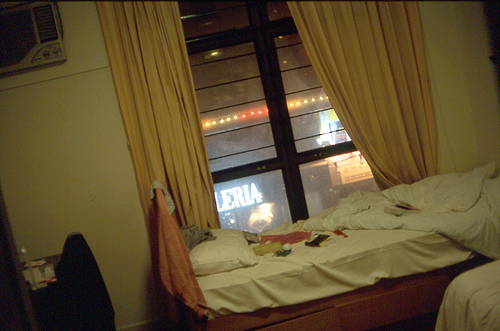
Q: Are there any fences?
A: No, there are no fences.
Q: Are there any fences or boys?
A: No, there are no fences or boys.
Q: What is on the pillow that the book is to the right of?
A: The shirt is on the pillow.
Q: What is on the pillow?
A: The shirt is on the pillow.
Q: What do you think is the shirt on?
A: The shirt is on the pillow.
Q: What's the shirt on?
A: The shirt is on the pillow.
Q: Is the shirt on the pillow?
A: Yes, the shirt is on the pillow.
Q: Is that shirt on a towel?
A: No, the shirt is on the pillow.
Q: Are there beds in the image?
A: Yes, there is a bed.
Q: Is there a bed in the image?
A: Yes, there is a bed.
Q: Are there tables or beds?
A: Yes, there is a bed.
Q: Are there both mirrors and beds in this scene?
A: No, there is a bed but no mirrors.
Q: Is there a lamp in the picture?
A: No, there are no lamps.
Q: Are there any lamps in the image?
A: No, there are no lamps.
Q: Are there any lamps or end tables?
A: No, there are no lamps or end tables.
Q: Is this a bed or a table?
A: This is a bed.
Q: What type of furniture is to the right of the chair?
A: The piece of furniture is a bed.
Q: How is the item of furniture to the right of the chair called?
A: The piece of furniture is a bed.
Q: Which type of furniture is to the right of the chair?
A: The piece of furniture is a bed.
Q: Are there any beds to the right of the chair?
A: Yes, there is a bed to the right of the chair.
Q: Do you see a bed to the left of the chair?
A: No, the bed is to the right of the chair.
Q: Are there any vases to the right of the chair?
A: No, there is a bed to the right of the chair.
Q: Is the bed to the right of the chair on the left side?
A: Yes, the bed is to the right of the chair.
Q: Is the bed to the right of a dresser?
A: No, the bed is to the right of the chair.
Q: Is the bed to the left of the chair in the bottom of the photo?
A: No, the bed is to the right of the chair.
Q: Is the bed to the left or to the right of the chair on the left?
A: The bed is to the right of the chair.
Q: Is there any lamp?
A: No, there are no lamps.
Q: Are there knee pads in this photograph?
A: No, there are no knee pads.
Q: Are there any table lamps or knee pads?
A: No, there are no knee pads or table lamps.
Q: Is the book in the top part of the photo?
A: No, the book is in the bottom of the image.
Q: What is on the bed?
A: The book is on the bed.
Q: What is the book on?
A: The book is on the bed.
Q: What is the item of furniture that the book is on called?
A: The piece of furniture is a bed.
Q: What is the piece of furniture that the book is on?
A: The piece of furniture is a bed.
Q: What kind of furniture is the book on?
A: The book is on the bed.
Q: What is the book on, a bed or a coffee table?
A: The book is on a bed.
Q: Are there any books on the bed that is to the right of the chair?
A: Yes, there is a book on the bed.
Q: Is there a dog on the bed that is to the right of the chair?
A: No, there is a book on the bed.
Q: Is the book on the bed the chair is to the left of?
A: Yes, the book is on the bed.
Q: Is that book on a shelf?
A: No, the book is on the bed.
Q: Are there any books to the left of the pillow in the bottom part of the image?
A: No, the book is to the right of the pillow.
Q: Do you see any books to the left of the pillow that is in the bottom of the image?
A: No, the book is to the right of the pillow.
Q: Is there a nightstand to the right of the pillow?
A: No, there is a book to the right of the pillow.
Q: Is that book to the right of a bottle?
A: No, the book is to the right of the pillow.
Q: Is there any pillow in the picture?
A: Yes, there is a pillow.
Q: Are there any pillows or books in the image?
A: Yes, there is a pillow.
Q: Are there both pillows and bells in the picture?
A: No, there is a pillow but no bells.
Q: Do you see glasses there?
A: No, there are no glasses.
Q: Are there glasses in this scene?
A: No, there are no glasses.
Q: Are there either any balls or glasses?
A: No, there are no glasses or balls.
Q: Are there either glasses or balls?
A: No, there are no glasses or balls.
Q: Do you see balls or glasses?
A: No, there are no glasses or balls.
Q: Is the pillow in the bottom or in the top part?
A: The pillow is in the bottom of the image.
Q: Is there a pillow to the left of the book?
A: Yes, there is a pillow to the left of the book.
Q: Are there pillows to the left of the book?
A: Yes, there is a pillow to the left of the book.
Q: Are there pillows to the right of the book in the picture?
A: No, the pillow is to the left of the book.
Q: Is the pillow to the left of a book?
A: Yes, the pillow is to the left of a book.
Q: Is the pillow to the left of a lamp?
A: No, the pillow is to the left of a book.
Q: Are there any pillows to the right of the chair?
A: Yes, there is a pillow to the right of the chair.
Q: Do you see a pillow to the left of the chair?
A: No, the pillow is to the right of the chair.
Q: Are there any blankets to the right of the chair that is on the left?
A: No, there is a pillow to the right of the chair.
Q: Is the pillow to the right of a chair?
A: Yes, the pillow is to the right of a chair.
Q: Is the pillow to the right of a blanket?
A: No, the pillow is to the right of a chair.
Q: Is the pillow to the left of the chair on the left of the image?
A: No, the pillow is to the right of the chair.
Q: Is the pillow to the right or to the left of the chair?
A: The pillow is to the right of the chair.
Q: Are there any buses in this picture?
A: No, there are no buses.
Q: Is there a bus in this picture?
A: No, there are no buses.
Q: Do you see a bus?
A: No, there are no buses.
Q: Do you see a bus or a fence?
A: No, there are no buses or fences.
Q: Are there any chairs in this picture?
A: Yes, there is a chair.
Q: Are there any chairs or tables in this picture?
A: Yes, there is a chair.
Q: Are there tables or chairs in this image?
A: Yes, there is a chair.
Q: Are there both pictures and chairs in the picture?
A: No, there is a chair but no pictures.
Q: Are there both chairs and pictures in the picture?
A: No, there is a chair but no pictures.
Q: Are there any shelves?
A: No, there are no shelves.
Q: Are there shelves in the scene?
A: No, there are no shelves.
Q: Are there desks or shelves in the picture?
A: No, there are no shelves or desks.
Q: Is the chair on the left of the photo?
A: Yes, the chair is on the left of the image.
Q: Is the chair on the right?
A: No, the chair is on the left of the image.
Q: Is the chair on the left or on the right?
A: The chair is on the left of the image.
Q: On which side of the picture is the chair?
A: The chair is on the left of the image.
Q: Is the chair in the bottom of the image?
A: Yes, the chair is in the bottom of the image.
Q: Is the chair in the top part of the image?
A: No, the chair is in the bottom of the image.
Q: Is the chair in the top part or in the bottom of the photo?
A: The chair is in the bottom of the image.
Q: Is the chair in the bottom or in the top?
A: The chair is in the bottom of the image.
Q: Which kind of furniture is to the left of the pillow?
A: The piece of furniture is a chair.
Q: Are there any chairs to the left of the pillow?
A: Yes, there is a chair to the left of the pillow.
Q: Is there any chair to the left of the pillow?
A: Yes, there is a chair to the left of the pillow.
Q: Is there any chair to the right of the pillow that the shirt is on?
A: No, the chair is to the left of the pillow.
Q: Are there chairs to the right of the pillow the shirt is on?
A: No, the chair is to the left of the pillow.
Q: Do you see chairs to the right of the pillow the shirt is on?
A: No, the chair is to the left of the pillow.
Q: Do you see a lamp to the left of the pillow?
A: No, there is a chair to the left of the pillow.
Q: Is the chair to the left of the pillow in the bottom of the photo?
A: Yes, the chair is to the left of the pillow.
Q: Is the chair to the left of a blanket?
A: No, the chair is to the left of the pillow.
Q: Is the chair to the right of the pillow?
A: No, the chair is to the left of the pillow.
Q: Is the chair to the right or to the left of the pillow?
A: The chair is to the left of the pillow.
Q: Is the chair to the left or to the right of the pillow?
A: The chair is to the left of the pillow.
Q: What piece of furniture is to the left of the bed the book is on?
A: The piece of furniture is a chair.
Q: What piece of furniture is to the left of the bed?
A: The piece of furniture is a chair.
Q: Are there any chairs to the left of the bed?
A: Yes, there is a chair to the left of the bed.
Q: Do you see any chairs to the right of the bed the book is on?
A: No, the chair is to the left of the bed.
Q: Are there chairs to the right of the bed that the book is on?
A: No, the chair is to the left of the bed.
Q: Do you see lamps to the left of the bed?
A: No, there is a chair to the left of the bed.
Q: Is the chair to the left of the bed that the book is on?
A: Yes, the chair is to the left of the bed.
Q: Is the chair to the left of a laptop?
A: No, the chair is to the left of the bed.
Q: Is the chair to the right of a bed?
A: No, the chair is to the left of a bed.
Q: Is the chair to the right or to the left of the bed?
A: The chair is to the left of the bed.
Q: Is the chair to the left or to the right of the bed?
A: The chair is to the left of the bed.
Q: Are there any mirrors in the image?
A: No, there are no mirrors.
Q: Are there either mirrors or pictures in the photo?
A: No, there are no mirrors or pictures.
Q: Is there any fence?
A: No, there are no fences.